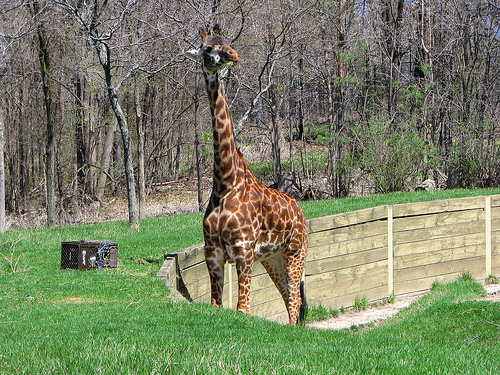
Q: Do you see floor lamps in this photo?
A: No, there are no floor lamps.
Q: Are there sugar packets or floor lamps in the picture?
A: No, there are no floor lamps or sugar packets.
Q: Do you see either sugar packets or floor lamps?
A: No, there are no floor lamps or sugar packets.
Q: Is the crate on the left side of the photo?
A: Yes, the crate is on the left of the image.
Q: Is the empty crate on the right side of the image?
A: No, the crate is on the left of the image.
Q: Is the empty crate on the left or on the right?
A: The crate is on the left of the image.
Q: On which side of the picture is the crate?
A: The crate is on the left of the image.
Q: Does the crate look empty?
A: Yes, the crate is empty.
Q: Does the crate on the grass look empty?
A: Yes, the crate is empty.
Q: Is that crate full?
A: No, the crate is empty.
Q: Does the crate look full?
A: No, the crate is empty.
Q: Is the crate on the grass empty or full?
A: The crate is empty.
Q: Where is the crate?
A: The crate is on the grass.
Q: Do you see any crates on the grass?
A: Yes, there is a crate on the grass.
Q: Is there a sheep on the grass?
A: No, there is a crate on the grass.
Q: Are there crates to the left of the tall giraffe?
A: Yes, there is a crate to the left of the giraffe.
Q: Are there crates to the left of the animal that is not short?
A: Yes, there is a crate to the left of the giraffe.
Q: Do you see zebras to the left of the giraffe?
A: No, there is a crate to the left of the giraffe.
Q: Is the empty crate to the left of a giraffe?
A: Yes, the crate is to the left of a giraffe.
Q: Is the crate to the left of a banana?
A: No, the crate is to the left of a giraffe.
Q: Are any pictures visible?
A: No, there are no pictures.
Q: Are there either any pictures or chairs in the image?
A: No, there are no pictures or chairs.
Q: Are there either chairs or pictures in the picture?
A: No, there are no pictures or chairs.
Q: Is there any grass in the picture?
A: Yes, there is grass.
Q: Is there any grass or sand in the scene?
A: Yes, there is grass.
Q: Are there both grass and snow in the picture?
A: No, there is grass but no snow.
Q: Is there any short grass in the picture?
A: Yes, there is short grass.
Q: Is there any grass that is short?
A: Yes, there is grass that is short.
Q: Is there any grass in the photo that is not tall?
A: Yes, there is short grass.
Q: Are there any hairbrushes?
A: No, there are no hairbrushes.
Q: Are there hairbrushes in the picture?
A: No, there are no hairbrushes.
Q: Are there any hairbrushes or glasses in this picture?
A: No, there are no hairbrushes or glasses.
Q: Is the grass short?
A: Yes, the grass is short.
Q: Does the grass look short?
A: Yes, the grass is short.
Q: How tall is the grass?
A: The grass is short.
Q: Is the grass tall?
A: No, the grass is short.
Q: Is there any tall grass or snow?
A: No, there is grass but it is short.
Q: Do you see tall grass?
A: No, there is grass but it is short.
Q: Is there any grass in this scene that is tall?
A: No, there is grass but it is short.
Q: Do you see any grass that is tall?
A: No, there is grass but it is short.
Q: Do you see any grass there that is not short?
A: No, there is grass but it is short.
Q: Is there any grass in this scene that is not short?
A: No, there is grass but it is short.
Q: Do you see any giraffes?
A: Yes, there is a giraffe.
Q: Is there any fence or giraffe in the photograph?
A: Yes, there is a giraffe.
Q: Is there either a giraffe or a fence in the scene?
A: Yes, there is a giraffe.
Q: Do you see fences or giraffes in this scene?
A: Yes, there is a giraffe.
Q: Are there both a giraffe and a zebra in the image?
A: No, there is a giraffe but no zebras.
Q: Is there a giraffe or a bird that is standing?
A: Yes, the giraffe is standing.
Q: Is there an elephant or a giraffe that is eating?
A: Yes, the giraffe is eating.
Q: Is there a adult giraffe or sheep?
A: Yes, there is an adult giraffe.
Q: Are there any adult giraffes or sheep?
A: Yes, there is an adult giraffe.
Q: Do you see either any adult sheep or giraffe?
A: Yes, there is an adult giraffe.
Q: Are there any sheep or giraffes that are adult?
A: Yes, the giraffe is adult.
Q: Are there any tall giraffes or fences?
A: Yes, there is a tall giraffe.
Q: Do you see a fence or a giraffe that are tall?
A: Yes, the giraffe is tall.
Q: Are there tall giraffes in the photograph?
A: Yes, there is a tall giraffe.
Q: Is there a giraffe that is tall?
A: Yes, there is a giraffe that is tall.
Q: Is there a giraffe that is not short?
A: Yes, there is a tall giraffe.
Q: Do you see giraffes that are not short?
A: Yes, there is a tall giraffe.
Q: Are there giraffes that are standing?
A: Yes, there is a giraffe that is standing.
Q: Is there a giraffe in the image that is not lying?
A: Yes, there is a giraffe that is standing.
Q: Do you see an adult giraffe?
A: Yes, there is an adult giraffe.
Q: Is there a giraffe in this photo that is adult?
A: Yes, there is a giraffe that is adult.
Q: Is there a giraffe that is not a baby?
A: Yes, there is a adult giraffe.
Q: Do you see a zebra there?
A: No, there are no zebras.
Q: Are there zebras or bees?
A: No, there are no zebras or bees.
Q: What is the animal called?
A: The animal is a giraffe.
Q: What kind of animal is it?
A: The animal is a giraffe.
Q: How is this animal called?
A: This is a giraffe.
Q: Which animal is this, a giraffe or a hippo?
A: This is a giraffe.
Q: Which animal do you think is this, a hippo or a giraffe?
A: This is a giraffe.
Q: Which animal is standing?
A: The animal is a giraffe.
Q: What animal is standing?
A: The animal is a giraffe.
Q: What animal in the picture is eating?
A: The animal is a giraffe.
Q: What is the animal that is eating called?
A: The animal is a giraffe.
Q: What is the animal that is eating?
A: The animal is a giraffe.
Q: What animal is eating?
A: The animal is a giraffe.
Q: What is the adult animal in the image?
A: The animal is a giraffe.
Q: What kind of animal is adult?
A: The animal is a giraffe.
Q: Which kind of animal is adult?
A: The animal is a giraffe.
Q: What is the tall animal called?
A: The animal is a giraffe.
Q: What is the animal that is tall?
A: The animal is a giraffe.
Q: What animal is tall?
A: The animal is a giraffe.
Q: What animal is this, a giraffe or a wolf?
A: This is a giraffe.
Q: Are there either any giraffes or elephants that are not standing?
A: No, there is a giraffe but it is standing.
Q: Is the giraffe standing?
A: Yes, the giraffe is standing.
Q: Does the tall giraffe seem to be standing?
A: Yes, the giraffe is standing.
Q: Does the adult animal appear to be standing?
A: Yes, the giraffe is standing.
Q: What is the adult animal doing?
A: The giraffe is standing.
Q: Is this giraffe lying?
A: No, the giraffe is standing.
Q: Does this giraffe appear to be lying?
A: No, the giraffe is standing.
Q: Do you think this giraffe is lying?
A: No, the giraffe is standing.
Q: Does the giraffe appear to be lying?
A: No, the giraffe is standing.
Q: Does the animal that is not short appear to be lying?
A: No, the giraffe is standing.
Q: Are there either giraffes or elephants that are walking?
A: No, there is a giraffe but it is standing.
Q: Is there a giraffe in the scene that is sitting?
A: No, there is a giraffe but it is standing.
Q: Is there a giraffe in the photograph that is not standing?
A: No, there is a giraffe but it is standing.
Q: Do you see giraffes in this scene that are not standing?
A: No, there is a giraffe but it is standing.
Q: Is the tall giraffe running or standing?
A: The giraffe is standing.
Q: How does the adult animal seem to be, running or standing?
A: The giraffe is standing.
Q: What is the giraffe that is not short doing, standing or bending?
A: The giraffe is standing.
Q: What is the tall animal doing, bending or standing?
A: The giraffe is standing.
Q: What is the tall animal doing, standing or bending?
A: The giraffe is standing.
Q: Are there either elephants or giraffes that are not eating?
A: No, there is a giraffe but it is eating.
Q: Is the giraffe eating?
A: Yes, the giraffe is eating.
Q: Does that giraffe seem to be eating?
A: Yes, the giraffe is eating.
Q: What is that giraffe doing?
A: The giraffe is eating.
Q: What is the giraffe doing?
A: The giraffe is eating.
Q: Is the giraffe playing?
A: No, the giraffe is eating.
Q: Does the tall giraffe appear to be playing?
A: No, the giraffe is eating.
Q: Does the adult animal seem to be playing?
A: No, the giraffe is eating.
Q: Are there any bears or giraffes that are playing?
A: No, there is a giraffe but it is eating.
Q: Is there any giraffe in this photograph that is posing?
A: No, there is a giraffe but it is eating.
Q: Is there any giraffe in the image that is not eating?
A: No, there is a giraffe but it is eating.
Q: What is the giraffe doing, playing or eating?
A: The giraffe is eating.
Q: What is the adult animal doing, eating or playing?
A: The giraffe is eating.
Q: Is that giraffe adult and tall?
A: Yes, the giraffe is adult and tall.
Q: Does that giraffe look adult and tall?
A: Yes, the giraffe is adult and tall.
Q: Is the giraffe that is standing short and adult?
A: No, the giraffe is adult but tall.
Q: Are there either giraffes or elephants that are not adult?
A: No, there is a giraffe but it is adult.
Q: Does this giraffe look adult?
A: Yes, the giraffe is adult.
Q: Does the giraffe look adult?
A: Yes, the giraffe is adult.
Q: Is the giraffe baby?
A: No, the giraffe is adult.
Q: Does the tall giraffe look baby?
A: No, the giraffe is adult.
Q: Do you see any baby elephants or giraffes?
A: No, there is a giraffe but it is adult.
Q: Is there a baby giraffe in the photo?
A: No, there is a giraffe but it is adult.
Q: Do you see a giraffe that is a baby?
A: No, there is a giraffe but it is adult.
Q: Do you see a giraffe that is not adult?
A: No, there is a giraffe but it is adult.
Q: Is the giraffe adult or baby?
A: The giraffe is adult.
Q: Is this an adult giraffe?
A: Yes, this is an adult giraffe.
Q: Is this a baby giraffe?
A: No, this is an adult giraffe.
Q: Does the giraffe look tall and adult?
A: Yes, the giraffe is tall and adult.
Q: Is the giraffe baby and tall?
A: No, the giraffe is tall but adult.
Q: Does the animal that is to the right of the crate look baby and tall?
A: No, the giraffe is tall but adult.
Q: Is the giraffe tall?
A: Yes, the giraffe is tall.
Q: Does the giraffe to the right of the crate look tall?
A: Yes, the giraffe is tall.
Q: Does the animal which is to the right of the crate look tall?
A: Yes, the giraffe is tall.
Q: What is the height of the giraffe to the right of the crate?
A: The giraffe is tall.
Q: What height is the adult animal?
A: The giraffe is tall.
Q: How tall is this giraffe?
A: The giraffe is tall.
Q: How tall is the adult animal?
A: The giraffe is tall.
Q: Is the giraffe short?
A: No, the giraffe is tall.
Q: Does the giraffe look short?
A: No, the giraffe is tall.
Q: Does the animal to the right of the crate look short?
A: No, the giraffe is tall.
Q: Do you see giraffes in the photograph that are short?
A: No, there is a giraffe but it is tall.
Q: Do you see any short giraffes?
A: No, there is a giraffe but it is tall.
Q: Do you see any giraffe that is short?
A: No, there is a giraffe but it is tall.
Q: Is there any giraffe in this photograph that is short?
A: No, there is a giraffe but it is tall.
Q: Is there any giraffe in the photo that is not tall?
A: No, there is a giraffe but it is tall.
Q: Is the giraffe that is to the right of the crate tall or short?
A: The giraffe is tall.